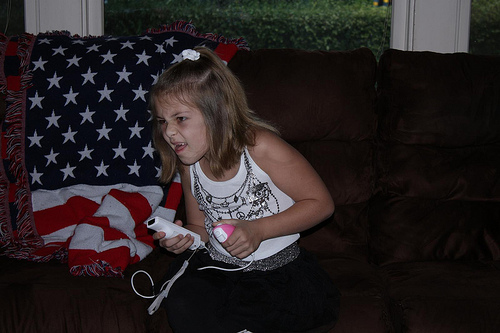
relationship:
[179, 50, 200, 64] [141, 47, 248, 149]
band holding hair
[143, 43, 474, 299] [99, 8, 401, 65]
couch in front of window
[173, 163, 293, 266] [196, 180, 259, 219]
tank top with necklaces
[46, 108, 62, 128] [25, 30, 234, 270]
star on the flag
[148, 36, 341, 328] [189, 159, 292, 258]
girl with a top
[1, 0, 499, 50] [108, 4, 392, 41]
window overlooking the hedges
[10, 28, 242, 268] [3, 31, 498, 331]
flag draped on the sofa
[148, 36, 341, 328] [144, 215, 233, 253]
girl playing game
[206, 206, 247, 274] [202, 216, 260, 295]
pink wii remote for wii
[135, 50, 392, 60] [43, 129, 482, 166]
window to shoe background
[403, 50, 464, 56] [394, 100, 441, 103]
frame of window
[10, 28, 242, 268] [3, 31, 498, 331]
flag over sofa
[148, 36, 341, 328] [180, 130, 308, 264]
girl wearing shirt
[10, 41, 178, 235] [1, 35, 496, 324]
flag on couch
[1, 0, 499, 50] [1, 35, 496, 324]
window behind couch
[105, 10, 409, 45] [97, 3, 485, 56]
hedges outside of window